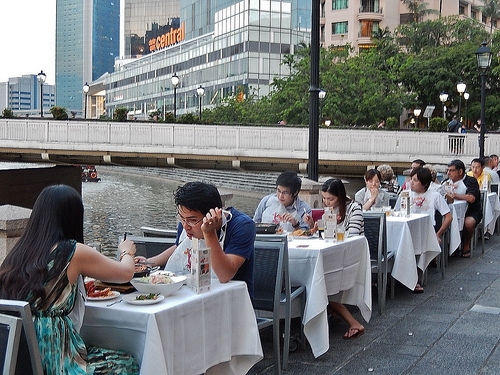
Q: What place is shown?
A: It is a city.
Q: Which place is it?
A: It is a city.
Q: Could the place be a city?
A: Yes, it is a city.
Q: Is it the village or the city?
A: It is the city.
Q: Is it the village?
A: No, it is the city.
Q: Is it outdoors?
A: Yes, it is outdoors.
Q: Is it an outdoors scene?
A: Yes, it is outdoors.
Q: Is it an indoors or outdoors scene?
A: It is outdoors.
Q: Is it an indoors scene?
A: No, it is outdoors.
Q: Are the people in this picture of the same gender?
A: No, they are both male and female.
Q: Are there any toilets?
A: No, there are no toilets.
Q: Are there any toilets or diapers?
A: No, there are no toilets or diapers.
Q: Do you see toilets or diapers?
A: No, there are no toilets or diapers.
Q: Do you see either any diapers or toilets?
A: No, there are no toilets or diapers.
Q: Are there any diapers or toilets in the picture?
A: No, there are no toilets or diapers.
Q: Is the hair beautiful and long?
A: Yes, the hair is beautiful and long.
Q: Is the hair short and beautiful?
A: No, the hair is beautiful but long.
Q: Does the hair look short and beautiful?
A: No, the hair is beautiful but long.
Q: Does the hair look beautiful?
A: Yes, the hair is beautiful.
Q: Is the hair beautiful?
A: Yes, the hair is beautiful.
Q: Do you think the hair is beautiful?
A: Yes, the hair is beautiful.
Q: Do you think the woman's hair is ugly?
A: No, the hair is beautiful.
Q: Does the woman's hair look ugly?
A: No, the hair is beautiful.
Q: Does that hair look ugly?
A: No, the hair is beautiful.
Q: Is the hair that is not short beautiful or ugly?
A: The hair is beautiful.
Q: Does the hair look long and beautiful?
A: Yes, the hair is long and beautiful.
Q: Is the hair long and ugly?
A: No, the hair is long but beautiful.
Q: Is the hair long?
A: Yes, the hair is long.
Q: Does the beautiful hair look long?
A: Yes, the hair is long.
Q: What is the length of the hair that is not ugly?
A: The hair is long.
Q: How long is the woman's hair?
A: The hair is long.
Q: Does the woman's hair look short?
A: No, the hair is long.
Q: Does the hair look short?
A: No, the hair is long.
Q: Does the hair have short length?
A: No, the hair is long.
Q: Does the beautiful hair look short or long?
A: The hair is long.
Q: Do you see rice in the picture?
A: Yes, there is rice.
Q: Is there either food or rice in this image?
A: Yes, there is rice.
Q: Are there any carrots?
A: No, there are no carrots.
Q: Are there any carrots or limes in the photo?
A: No, there are no carrots or limes.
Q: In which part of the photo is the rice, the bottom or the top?
A: The rice is in the bottom of the image.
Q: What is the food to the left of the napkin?
A: The food is rice.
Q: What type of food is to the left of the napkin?
A: The food is rice.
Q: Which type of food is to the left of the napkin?
A: The food is rice.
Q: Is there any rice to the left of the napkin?
A: Yes, there is rice to the left of the napkin.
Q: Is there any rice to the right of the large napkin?
A: No, the rice is to the left of the napkin.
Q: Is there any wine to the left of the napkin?
A: No, there is rice to the left of the napkin.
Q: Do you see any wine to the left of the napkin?
A: No, there is rice to the left of the napkin.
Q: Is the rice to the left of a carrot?
A: No, the rice is to the left of the napkin.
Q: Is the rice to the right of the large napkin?
A: No, the rice is to the left of the napkin.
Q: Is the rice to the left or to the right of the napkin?
A: The rice is to the left of the napkin.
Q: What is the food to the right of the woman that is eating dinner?
A: The food is rice.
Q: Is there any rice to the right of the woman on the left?
A: Yes, there is rice to the right of the woman.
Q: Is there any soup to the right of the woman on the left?
A: No, there is rice to the right of the woman.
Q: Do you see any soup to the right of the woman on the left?
A: No, there is rice to the right of the woman.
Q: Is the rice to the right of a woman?
A: Yes, the rice is to the right of a woman.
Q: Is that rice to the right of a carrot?
A: No, the rice is to the right of a woman.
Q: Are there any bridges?
A: Yes, there is a bridge.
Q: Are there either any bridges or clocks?
A: Yes, there is a bridge.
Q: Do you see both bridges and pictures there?
A: No, there is a bridge but no pictures.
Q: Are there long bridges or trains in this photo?
A: Yes, there is a long bridge.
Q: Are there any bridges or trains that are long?
A: Yes, the bridge is long.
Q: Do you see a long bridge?
A: Yes, there is a long bridge.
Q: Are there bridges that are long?
A: Yes, there is a bridge that is long.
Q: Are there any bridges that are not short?
A: Yes, there is a long bridge.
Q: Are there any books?
A: No, there are no books.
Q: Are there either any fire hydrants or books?
A: No, there are no books or fire hydrants.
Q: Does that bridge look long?
A: Yes, the bridge is long.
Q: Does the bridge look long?
A: Yes, the bridge is long.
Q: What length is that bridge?
A: The bridge is long.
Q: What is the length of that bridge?
A: The bridge is long.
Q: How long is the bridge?
A: The bridge is long.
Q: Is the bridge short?
A: No, the bridge is long.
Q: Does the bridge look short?
A: No, the bridge is long.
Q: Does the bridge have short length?
A: No, the bridge is long.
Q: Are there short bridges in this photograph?
A: No, there is a bridge but it is long.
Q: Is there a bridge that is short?
A: No, there is a bridge but it is long.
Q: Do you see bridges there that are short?
A: No, there is a bridge but it is long.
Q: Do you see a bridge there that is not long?
A: No, there is a bridge but it is long.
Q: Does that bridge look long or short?
A: The bridge is long.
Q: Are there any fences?
A: No, there are no fences.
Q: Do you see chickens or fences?
A: No, there are no fences or chickens.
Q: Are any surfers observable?
A: No, there are no surfers.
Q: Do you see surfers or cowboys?
A: No, there are no surfers or cowboys.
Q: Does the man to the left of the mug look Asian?
A: Yes, the man is asian.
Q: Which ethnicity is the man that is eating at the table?
A: The man is asian.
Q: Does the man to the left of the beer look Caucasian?
A: No, the man is asian.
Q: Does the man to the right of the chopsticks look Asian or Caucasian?
A: The man is asian.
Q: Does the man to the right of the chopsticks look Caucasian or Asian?
A: The man is asian.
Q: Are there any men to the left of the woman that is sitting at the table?
A: Yes, there is a man to the left of the woman.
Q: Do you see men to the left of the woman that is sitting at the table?
A: Yes, there is a man to the left of the woman.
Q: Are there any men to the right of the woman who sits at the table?
A: No, the man is to the left of the woman.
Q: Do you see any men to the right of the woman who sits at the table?
A: No, the man is to the left of the woman.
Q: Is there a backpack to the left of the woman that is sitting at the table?
A: No, there is a man to the left of the woman.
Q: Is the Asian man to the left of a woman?
A: Yes, the man is to the left of a woman.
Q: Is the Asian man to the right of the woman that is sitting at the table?
A: No, the man is to the left of the woman.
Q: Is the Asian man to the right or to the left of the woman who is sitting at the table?
A: The man is to the left of the woman.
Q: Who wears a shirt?
A: The man wears a shirt.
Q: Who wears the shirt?
A: The man wears a shirt.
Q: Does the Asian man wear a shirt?
A: Yes, the man wears a shirt.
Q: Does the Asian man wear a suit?
A: No, the man wears a shirt.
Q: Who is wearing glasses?
A: The man is wearing glasses.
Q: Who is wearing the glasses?
A: The man is wearing glasses.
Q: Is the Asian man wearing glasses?
A: Yes, the man is wearing glasses.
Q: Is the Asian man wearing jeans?
A: No, the man is wearing glasses.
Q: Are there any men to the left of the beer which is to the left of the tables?
A: Yes, there is a man to the left of the beer.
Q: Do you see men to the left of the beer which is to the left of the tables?
A: Yes, there is a man to the left of the beer.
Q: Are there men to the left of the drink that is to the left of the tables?
A: Yes, there is a man to the left of the beer.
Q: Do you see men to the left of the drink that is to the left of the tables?
A: Yes, there is a man to the left of the beer.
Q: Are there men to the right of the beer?
A: No, the man is to the left of the beer.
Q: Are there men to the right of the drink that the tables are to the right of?
A: No, the man is to the left of the beer.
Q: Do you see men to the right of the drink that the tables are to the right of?
A: No, the man is to the left of the beer.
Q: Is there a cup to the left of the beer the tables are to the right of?
A: No, there is a man to the left of the beer.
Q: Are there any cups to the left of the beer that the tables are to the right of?
A: No, there is a man to the left of the beer.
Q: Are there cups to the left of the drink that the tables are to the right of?
A: No, there is a man to the left of the beer.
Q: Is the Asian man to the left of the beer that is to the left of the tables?
A: Yes, the man is to the left of the beer.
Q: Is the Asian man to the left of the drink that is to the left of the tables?
A: Yes, the man is to the left of the beer.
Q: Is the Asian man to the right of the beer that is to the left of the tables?
A: No, the man is to the left of the beer.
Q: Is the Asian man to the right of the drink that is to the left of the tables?
A: No, the man is to the left of the beer.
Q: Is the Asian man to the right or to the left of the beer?
A: The man is to the left of the beer.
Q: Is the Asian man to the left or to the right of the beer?
A: The man is to the left of the beer.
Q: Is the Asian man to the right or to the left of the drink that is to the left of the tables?
A: The man is to the left of the beer.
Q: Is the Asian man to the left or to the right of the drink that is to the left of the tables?
A: The man is to the left of the beer.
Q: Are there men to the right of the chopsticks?
A: Yes, there is a man to the right of the chopsticks.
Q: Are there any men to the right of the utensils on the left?
A: Yes, there is a man to the right of the chopsticks.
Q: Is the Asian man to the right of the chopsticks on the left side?
A: Yes, the man is to the right of the chopsticks.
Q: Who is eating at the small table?
A: The man is eating at the table.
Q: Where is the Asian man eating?
A: The man is eating at the table.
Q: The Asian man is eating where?
A: The man is eating at the table.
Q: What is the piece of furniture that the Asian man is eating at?
A: The piece of furniture is a table.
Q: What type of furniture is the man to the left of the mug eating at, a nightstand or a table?
A: The man is eating at a table.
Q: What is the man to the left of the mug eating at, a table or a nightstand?
A: The man is eating at a table.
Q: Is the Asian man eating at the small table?
A: Yes, the man is eating at the table.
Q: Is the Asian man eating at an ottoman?
A: No, the man is eating at the table.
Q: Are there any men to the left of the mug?
A: Yes, there is a man to the left of the mug.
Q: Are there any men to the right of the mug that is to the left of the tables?
A: No, the man is to the left of the mug.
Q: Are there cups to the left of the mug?
A: No, there is a man to the left of the mug.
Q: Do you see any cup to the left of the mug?
A: No, there is a man to the left of the mug.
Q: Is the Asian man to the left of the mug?
A: Yes, the man is to the left of the mug.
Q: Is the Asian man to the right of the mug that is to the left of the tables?
A: No, the man is to the left of the mug.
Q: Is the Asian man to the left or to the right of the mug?
A: The man is to the left of the mug.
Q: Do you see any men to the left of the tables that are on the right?
A: Yes, there is a man to the left of the tables.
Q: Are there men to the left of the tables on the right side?
A: Yes, there is a man to the left of the tables.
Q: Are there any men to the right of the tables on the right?
A: No, the man is to the left of the tables.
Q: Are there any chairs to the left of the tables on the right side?
A: No, there is a man to the left of the tables.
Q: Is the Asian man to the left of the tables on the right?
A: Yes, the man is to the left of the tables.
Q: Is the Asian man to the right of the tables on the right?
A: No, the man is to the left of the tables.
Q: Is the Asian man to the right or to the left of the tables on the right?
A: The man is to the left of the tables.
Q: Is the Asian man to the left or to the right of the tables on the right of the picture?
A: The man is to the left of the tables.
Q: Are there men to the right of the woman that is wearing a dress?
A: Yes, there is a man to the right of the woman.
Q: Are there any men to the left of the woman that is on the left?
A: No, the man is to the right of the woman.